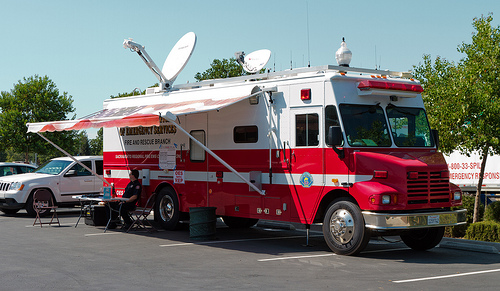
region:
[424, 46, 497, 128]
The tree is leafy.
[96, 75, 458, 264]
The truck is white and red.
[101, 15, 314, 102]
The dishes are on the truck.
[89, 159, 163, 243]
The man is sitting.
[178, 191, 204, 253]
The trash is green.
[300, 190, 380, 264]
The tire is black.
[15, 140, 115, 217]
The car is white.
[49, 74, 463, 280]
The truck is parked.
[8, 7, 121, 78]
The sky is clear.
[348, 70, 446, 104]
The light is red.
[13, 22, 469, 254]
red ambulance parked in lot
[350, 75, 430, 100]
emergency lights on front of truck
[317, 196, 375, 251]
black front tire of a truck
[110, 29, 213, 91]
satellite dish on an ambulance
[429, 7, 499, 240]
green tree by parking lot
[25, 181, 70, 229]
chair in a parking lot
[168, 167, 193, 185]
sign on an ambulance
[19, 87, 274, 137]
awning along side of ambulance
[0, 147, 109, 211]
white car parked in a lot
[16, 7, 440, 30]
blue sky in the distance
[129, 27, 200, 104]
a white dish receiver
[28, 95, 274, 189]
a red and white canopy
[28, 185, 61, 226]
a folding chair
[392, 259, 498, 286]
a long white line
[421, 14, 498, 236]
a tall green tree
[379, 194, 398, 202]
a headlight of a truck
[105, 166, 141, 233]
a man sitting in a chair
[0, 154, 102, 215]
a white suv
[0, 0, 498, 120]
a clear blue sky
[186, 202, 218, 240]
a small black trashcan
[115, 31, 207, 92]
The dish is white.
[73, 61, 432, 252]
The truck is red and white.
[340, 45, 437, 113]
The light is red.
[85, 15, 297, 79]
Two dishes are on the truck.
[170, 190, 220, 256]
The trash is green.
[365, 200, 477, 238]
The bumper is metal.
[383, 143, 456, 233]
The grill is red.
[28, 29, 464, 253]
big, red and white truck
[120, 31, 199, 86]
large white satellite on truck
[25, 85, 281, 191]
awning on side of truck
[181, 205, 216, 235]
dark container next to truck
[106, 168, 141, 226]
man sitting under awning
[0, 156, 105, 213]
white care behind truck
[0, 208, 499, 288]
clean, gray concrete ground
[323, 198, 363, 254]
front wheel of truck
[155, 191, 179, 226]
back wheel of truck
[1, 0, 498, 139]
blue, cloudless sky